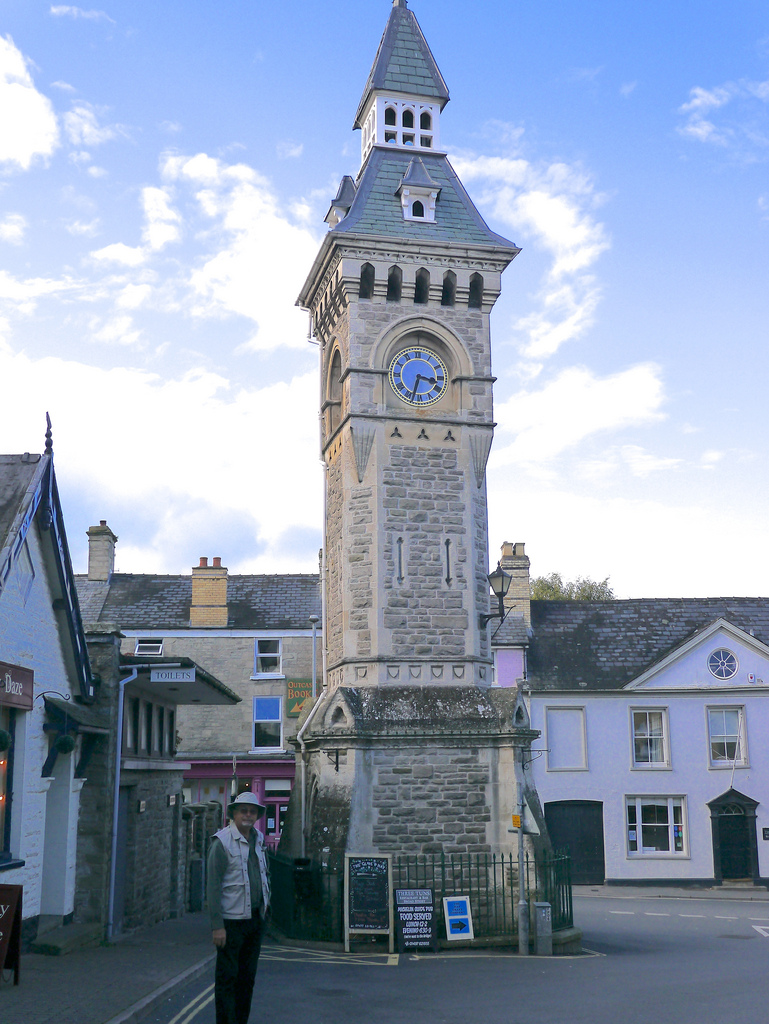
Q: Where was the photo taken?
A: Near a monument.